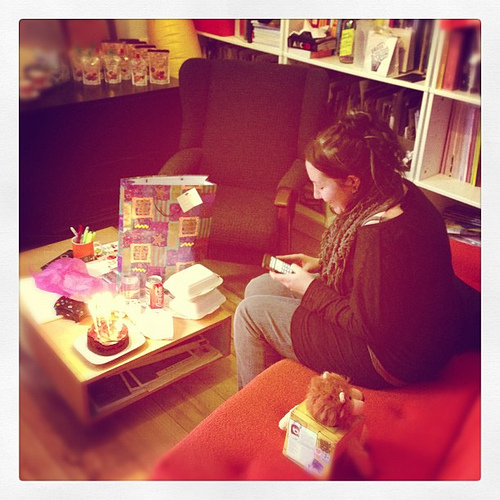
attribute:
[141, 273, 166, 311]
can — Coca Cola, red, white